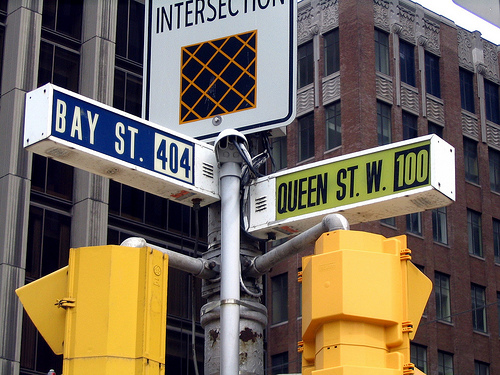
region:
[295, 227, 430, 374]
Yellow traffic light under street sign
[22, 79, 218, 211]
Blue and white street sign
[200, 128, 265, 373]
Silver metal pole holding street signs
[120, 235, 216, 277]
Metal pole holding yellow traffic light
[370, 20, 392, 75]
Window on building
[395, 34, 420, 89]
Window on building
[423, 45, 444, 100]
Window on building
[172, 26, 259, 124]
Grid is blue and orange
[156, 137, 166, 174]
Number 4 on street sign is blue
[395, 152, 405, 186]
Number 1 on street sign is green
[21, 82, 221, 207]
The blue stree sign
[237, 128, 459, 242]
The yellow street sign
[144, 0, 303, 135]
White rectangular sign with an orange and black square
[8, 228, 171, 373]
The yellow street light on the left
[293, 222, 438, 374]
The yellow street light on the right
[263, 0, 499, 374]
The red building in the background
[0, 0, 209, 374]
The white cement building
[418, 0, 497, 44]
The sky between rooftops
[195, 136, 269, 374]
The large pole holding the street lights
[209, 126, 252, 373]
The small pole with wires coming out of it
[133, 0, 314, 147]
yellow and white sign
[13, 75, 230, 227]
blue and white sign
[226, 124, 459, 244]
green and white sign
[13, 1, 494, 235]
street signs on a pole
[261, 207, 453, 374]
bright yellow traffic signal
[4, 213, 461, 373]
pair of yellow traffic signals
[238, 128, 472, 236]
street sign for queen st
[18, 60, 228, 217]
street sign for bay st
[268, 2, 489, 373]
large brick building with windows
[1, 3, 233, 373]
large block building with windows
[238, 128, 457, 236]
Electric street sign for Queen Street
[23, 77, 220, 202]
Electric street sign for Bay Street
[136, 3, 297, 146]
Traffic sign on top of the pole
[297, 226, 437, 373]
Street signal light attached to pipe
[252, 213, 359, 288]
Pipe with wires for the street light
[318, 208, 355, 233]
90 degrees pipefitting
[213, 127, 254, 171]
Weatherproof top of electrical conduit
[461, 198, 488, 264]
Window in a building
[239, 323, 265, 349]
Rust on a pole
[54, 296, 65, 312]
Wingnut fastener on streetlight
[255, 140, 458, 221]
a sign says queen st.100.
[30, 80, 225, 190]
a blue and white street sign.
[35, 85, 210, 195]
a street sign says bay st.404.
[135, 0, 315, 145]
a sign says intersection.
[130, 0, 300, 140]
a white yellow and black street sign.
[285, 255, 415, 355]
a yellow street light.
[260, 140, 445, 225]
a yellow and black street sign.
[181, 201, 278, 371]
a grey pole is holding up the street signs.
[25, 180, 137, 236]
a black and grey building.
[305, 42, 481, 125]
a big brown building.